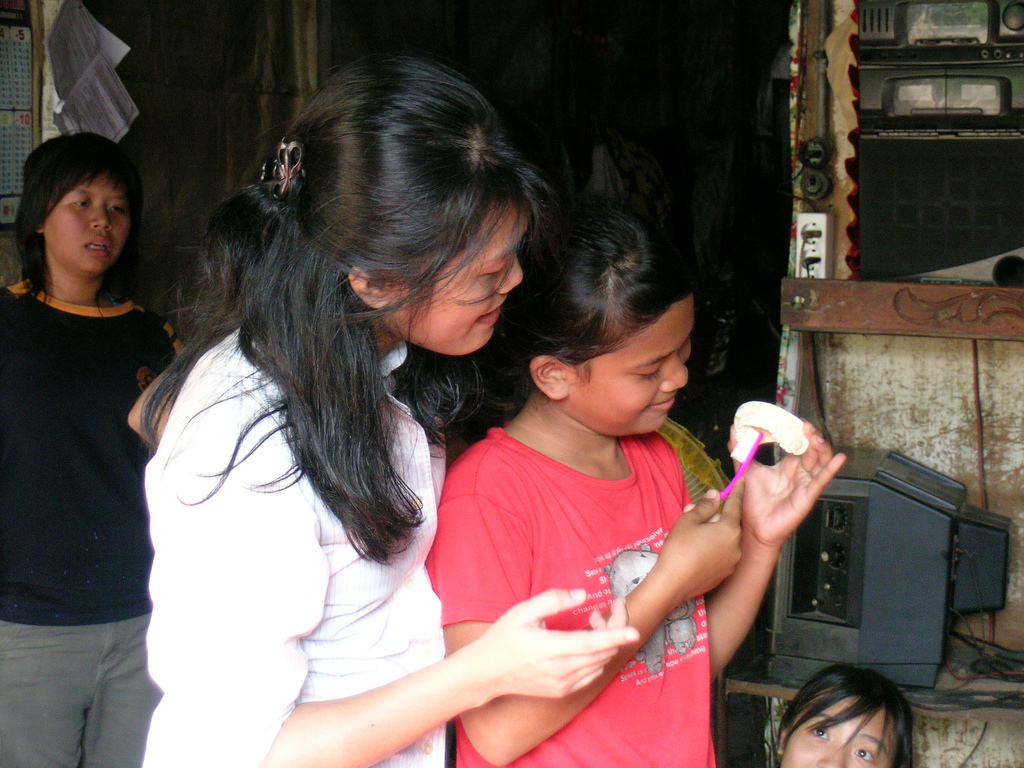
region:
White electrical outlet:
[789, 212, 848, 282]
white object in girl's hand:
[721, 407, 807, 464]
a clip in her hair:
[255, 129, 323, 212]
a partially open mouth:
[70, 230, 119, 269]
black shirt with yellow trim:
[2, 268, 177, 623]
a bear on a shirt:
[591, 516, 718, 691]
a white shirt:
[133, 342, 443, 764]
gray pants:
[0, 616, 150, 766]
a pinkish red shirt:
[451, 426, 728, 766]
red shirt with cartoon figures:
[416, 404, 729, 766]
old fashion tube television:
[741, 409, 1021, 692]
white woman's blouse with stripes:
[128, 312, 462, 766]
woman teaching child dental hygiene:
[122, 49, 851, 765]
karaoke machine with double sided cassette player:
[836, 0, 1017, 305]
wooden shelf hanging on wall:
[771, 258, 1021, 344]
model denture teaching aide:
[719, 387, 817, 468]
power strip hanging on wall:
[760, 195, 837, 350]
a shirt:
[500, 487, 576, 557]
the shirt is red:
[468, 494, 582, 581]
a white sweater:
[180, 557, 283, 643]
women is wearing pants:
[4, 629, 151, 754]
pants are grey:
[9, 658, 107, 763]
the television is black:
[809, 529, 909, 631]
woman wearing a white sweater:
[126, 50, 638, 767]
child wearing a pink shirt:
[438, 194, 844, 767]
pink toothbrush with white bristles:
[712, 427, 760, 500]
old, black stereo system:
[843, 4, 1022, 284]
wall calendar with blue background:
[4, 3, 43, 229]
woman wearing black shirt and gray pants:
[2, 133, 193, 767]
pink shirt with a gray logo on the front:
[425, 409, 720, 765]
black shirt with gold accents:
[4, 279, 183, 633]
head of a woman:
[266, 84, 526, 369]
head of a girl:
[514, 202, 712, 450]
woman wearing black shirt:
[17, 120, 182, 756]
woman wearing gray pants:
[10, 126, 185, 766]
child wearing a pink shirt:
[454, 198, 743, 762]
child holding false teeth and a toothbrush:
[459, 179, 815, 767]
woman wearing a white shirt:
[114, 26, 482, 766]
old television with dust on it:
[753, 399, 1019, 726]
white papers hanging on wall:
[49, 9, 142, 158]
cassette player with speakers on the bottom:
[848, 13, 1011, 283]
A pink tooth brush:
[712, 424, 767, 498]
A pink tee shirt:
[425, 421, 716, 766]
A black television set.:
[768, 441, 1013, 692]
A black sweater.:
[0, 279, 193, 627]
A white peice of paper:
[42, 1, 131, 100]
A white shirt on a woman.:
[139, 332, 447, 766]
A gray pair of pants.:
[0, 621, 165, 765]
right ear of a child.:
[528, 352, 574, 401]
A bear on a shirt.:
[601, 542, 694, 673]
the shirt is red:
[466, 447, 723, 754]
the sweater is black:
[13, 296, 165, 611]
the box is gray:
[792, 430, 995, 707]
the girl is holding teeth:
[721, 409, 823, 476]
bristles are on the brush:
[729, 427, 768, 472]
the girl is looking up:
[787, 681, 863, 757]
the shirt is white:
[190, 373, 451, 759]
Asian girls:
[18, 72, 952, 766]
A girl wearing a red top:
[446, 214, 731, 765]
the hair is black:
[136, 59, 551, 573]